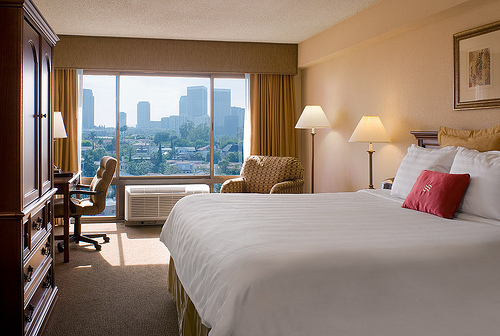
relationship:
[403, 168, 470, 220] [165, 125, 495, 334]
pillow on bed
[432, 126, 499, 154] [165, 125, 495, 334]
pillow on bed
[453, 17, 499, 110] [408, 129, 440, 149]
art on top of headboard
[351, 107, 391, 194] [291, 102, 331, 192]
lamp next to lamp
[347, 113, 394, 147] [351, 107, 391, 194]
shade on lamp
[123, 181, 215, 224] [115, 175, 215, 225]
air conditioner on wall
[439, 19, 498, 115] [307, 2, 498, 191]
picture on wall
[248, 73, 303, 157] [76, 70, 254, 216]
curtain on window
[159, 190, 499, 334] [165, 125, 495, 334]
sheet on bed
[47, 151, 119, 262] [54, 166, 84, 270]
chair at desk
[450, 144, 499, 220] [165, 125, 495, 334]
pillow on bed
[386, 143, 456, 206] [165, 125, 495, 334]
pillow on bed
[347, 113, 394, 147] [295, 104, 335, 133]
shade on shade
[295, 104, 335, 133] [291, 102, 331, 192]
shade on lamp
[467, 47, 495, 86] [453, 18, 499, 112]
picture in frame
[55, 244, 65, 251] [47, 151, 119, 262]
wheel on chair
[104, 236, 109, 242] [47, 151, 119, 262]
wheel on chair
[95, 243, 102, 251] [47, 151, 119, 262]
wheel on chair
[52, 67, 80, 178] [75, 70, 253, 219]
curtain on window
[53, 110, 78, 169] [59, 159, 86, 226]
lamp on desk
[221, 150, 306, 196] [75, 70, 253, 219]
chair next to window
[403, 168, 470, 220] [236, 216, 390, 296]
pillow on bed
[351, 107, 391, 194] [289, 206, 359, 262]
lamp near bed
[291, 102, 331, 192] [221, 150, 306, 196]
lamp next to chair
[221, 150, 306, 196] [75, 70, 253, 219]
chair near window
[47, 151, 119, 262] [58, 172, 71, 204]
chair next to desk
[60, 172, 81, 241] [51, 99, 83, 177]
lamp next to desk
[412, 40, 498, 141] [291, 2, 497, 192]
picture on wall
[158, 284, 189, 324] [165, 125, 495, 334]
bed skirt on bed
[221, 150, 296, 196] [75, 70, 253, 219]
chair next to window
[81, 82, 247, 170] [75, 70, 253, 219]
skyline through window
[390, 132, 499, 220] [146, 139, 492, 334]
pillows are on bed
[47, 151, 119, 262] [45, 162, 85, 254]
chair pushed into a desk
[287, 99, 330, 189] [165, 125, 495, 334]
light next to bed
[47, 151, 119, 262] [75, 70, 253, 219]
chair next to window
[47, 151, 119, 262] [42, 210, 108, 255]
chair has legs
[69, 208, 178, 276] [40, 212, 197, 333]
light hitting carpet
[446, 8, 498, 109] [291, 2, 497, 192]
painting hanging on wall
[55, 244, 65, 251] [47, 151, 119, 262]
wheel are under chair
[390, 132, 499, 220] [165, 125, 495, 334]
pillows are on bed